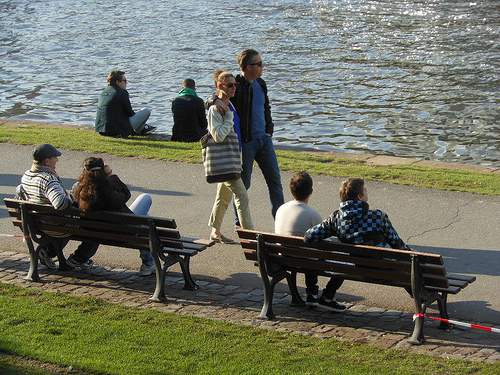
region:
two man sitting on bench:
[271, 170, 412, 310]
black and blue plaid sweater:
[305, 200, 416, 251]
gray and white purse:
[204, 95, 242, 184]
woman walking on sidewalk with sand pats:
[204, 69, 256, 246]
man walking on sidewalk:
[229, 49, 286, 235]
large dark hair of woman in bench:
[71, 163, 111, 214]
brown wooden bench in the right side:
[235, 227, 473, 324]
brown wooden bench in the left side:
[0, 196, 217, 286]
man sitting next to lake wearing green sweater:
[96, 70, 156, 137]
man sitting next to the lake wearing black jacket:
[172, 78, 209, 138]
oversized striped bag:
[197, 125, 244, 182]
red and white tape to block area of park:
[413, 301, 496, 346]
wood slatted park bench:
[225, 217, 463, 324]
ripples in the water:
[1, 1, 498, 163]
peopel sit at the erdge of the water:
[93, 49, 216, 137]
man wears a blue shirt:
[246, 69, 274, 139]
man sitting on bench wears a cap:
[28, 138, 68, 171]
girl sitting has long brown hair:
[64, 152, 154, 212]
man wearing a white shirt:
[274, 168, 317, 248]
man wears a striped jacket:
[11, 155, 71, 216]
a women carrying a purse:
[200, 138, 245, 184]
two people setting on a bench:
[272, 181, 390, 242]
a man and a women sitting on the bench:
[22, 147, 129, 204]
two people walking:
[205, 53, 283, 196]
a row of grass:
[36, 306, 166, 363]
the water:
[324, 19, 491, 110]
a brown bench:
[240, 246, 438, 293]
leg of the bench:
[143, 248, 175, 300]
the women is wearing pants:
[215, 184, 252, 226]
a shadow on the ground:
[454, 242, 489, 281]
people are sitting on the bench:
[13, 131, 210, 306]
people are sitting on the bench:
[213, 153, 498, 331]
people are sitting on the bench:
[19, 142, 141, 259]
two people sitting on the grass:
[81, 40, 251, 197]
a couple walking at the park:
[179, 39, 326, 299]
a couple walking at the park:
[161, 22, 288, 233]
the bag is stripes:
[198, 107, 251, 197]